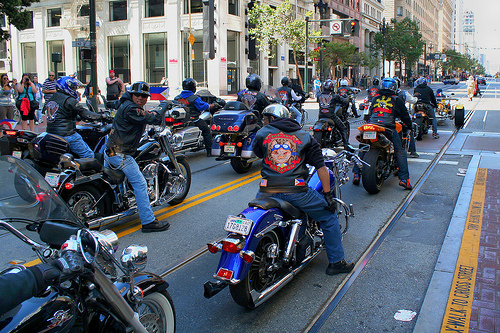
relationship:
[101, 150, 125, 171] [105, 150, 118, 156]
chain attached to wallet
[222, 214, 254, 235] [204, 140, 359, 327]
license plate wearing motorcycle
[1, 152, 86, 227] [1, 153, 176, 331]
windshield of motorcycle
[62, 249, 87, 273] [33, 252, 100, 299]
glove on hand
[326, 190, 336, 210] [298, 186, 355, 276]
hand on leg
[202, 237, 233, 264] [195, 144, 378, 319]
light from motorcycle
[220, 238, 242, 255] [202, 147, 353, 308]
brake light of motorcycle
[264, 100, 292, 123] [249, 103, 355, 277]
helmet on man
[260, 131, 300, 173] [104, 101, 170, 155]
design on back of leather jacket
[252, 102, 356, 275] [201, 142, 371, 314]
riders riding motorbike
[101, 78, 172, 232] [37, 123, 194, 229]
person riding motorbike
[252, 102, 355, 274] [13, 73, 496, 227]
riders at stop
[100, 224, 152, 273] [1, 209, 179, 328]
lights on motorcycle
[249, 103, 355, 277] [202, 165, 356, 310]
man on motorcycle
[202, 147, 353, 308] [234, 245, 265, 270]
motorcycle has light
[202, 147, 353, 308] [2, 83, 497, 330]
motorcycle going down road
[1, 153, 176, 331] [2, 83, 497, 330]
motorcycle going down road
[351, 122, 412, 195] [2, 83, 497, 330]
motorcycle going down road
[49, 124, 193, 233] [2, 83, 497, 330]
motorcycle going down road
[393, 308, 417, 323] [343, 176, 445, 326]
trash on ground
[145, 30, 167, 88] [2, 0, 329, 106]
windows of a building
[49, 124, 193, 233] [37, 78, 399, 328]
motorcycle on street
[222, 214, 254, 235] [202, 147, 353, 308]
license plate on a motorcycle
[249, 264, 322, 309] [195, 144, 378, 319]
muffler of a motorcycle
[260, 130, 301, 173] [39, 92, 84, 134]
design on back of jacket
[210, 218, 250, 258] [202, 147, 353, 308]
red lights on motorcycle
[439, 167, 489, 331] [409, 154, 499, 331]
line on a sidewalk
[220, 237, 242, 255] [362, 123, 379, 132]
brake light of a brake light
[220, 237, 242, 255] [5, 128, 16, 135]
brake light of a brake light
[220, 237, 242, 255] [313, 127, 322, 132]
brake light of a brake light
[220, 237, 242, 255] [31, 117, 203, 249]
brake light of a motorcycle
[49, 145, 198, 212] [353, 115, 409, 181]
motorcycle of a motorcycle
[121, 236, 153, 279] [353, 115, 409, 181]
headlight light of a motorcycle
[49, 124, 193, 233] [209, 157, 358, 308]
motorcycle of a motorcycle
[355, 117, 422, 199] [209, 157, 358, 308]
motorcycle of a motorcycle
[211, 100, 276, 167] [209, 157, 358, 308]
motorcycle of a motorcycle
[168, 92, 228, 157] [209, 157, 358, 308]
motorcycle of a motorcycle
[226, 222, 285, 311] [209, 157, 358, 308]
wheel of a motorcycle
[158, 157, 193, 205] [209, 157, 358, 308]
wheel of a motorcycle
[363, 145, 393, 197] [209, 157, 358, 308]
wheel of a motorcycle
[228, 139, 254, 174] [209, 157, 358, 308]
wheel of a motorcycle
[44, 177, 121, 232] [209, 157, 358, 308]
wheel of a motorcycle